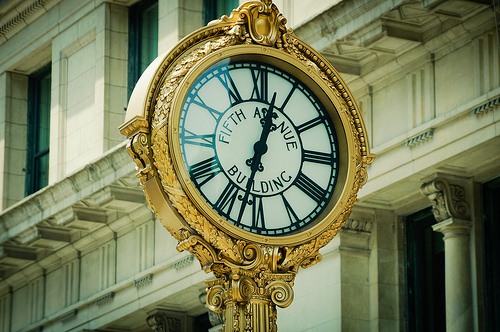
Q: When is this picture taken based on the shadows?
A: Daytime.